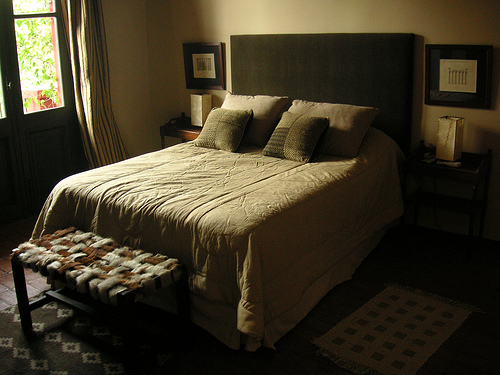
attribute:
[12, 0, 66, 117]
window — tan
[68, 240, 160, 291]
strips — thick, woven, brown, white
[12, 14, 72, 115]
pane — glass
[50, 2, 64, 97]
railing — red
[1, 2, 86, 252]
door — clear, dark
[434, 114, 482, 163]
lampshade — short, rectangular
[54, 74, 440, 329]
bed — four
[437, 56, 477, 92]
image — framed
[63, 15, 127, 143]
curtain — striped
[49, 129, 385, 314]
comforter — tan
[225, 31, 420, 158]
head board — green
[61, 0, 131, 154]
curtain — long, stripes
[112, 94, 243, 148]
night table — wooden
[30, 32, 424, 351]
bed — made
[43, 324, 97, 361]
pattern — white, diamond